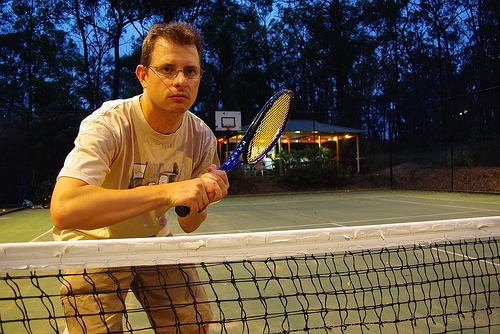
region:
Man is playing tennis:
[30, 19, 330, 231]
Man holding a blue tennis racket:
[217, 88, 332, 211]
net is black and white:
[290, 257, 479, 331]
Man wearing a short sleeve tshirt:
[50, 93, 247, 245]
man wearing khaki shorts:
[43, 260, 222, 325]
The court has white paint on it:
[287, 190, 403, 243]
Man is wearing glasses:
[143, 55, 218, 92]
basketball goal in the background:
[205, 82, 264, 177]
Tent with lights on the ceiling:
[220, 98, 367, 170]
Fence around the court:
[368, 118, 493, 160]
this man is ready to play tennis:
[20, 9, 457, 333]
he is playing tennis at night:
[12, 4, 476, 213]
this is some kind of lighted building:
[206, 98, 374, 192]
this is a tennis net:
[3, 225, 499, 329]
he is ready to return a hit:
[116, 23, 304, 234]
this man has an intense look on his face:
[105, 1, 221, 116]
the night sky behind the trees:
[0, 5, 125, 94]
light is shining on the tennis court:
[15, 196, 484, 321]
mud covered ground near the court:
[390, 143, 495, 203]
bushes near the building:
[285, 151, 358, 195]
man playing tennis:
[37, 18, 278, 323]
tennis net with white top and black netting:
[0, 220, 499, 331]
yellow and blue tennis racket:
[175, 78, 297, 223]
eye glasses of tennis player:
[140, 59, 202, 79]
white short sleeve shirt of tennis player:
[45, 96, 224, 243]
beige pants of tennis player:
[52, 253, 214, 333]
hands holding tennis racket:
[174, 163, 231, 219]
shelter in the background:
[217, 108, 360, 184]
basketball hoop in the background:
[214, 107, 243, 186]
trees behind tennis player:
[10, 5, 497, 161]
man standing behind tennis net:
[37, 12, 299, 321]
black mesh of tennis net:
[0, 245, 491, 332]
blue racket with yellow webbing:
[174, 77, 308, 219]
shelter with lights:
[220, 104, 362, 181]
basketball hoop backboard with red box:
[214, 108, 244, 133]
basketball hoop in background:
[210, 104, 250, 193]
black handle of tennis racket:
[172, 194, 193, 219]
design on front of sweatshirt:
[122, 156, 189, 183]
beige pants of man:
[55, 255, 212, 332]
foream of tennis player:
[52, 177, 208, 224]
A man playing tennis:
[75, 15, 241, 222]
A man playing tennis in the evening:
[104, 18, 319, 213]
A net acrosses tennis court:
[44, 217, 475, 330]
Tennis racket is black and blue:
[220, 79, 298, 183]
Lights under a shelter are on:
[287, 122, 364, 163]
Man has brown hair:
[141, 17, 203, 116]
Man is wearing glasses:
[126, 12, 208, 123]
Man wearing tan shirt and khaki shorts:
[67, 83, 182, 318]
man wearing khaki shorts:
[115, 143, 245, 314]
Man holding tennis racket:
[114, 31, 341, 226]